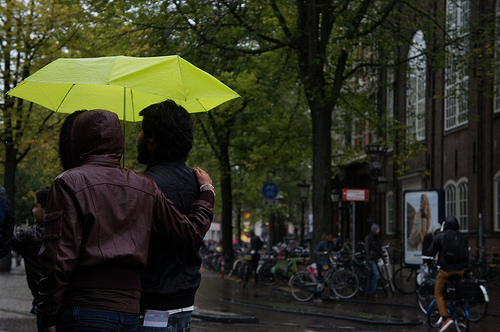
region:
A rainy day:
[12, 10, 472, 310]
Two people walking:
[16, 105, 236, 313]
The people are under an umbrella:
[17, 39, 228, 316]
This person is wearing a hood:
[52, 100, 128, 175]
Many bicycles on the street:
[219, 201, 361, 320]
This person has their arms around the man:
[42, 98, 154, 325]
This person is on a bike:
[410, 209, 479, 316]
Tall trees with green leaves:
[218, 9, 358, 256]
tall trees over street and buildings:
[1, 2, 407, 232]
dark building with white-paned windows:
[311, 0, 491, 291]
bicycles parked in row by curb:
[206, 230, 396, 305]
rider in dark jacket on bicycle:
[406, 212, 496, 323]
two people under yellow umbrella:
[10, 26, 240, 321]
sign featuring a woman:
[397, 182, 439, 263]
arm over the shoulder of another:
[17, 95, 218, 325]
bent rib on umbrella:
[6, 45, 237, 120]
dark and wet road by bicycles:
[177, 252, 372, 324]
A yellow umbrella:
[76, 62, 186, 79]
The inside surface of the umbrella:
[83, 91, 113, 106]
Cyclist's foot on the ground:
[441, 326, 445, 329]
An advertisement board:
[407, 193, 437, 230]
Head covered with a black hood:
[448, 218, 457, 226]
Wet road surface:
[267, 313, 282, 319]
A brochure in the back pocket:
[148, 311, 163, 326]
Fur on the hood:
[61, 128, 68, 155]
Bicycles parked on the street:
[278, 247, 301, 262]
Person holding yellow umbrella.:
[45, 39, 186, 94]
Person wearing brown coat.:
[83, 182, 144, 264]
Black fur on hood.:
[57, 118, 82, 153]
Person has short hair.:
[153, 118, 193, 158]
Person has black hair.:
[149, 102, 196, 149]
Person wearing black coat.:
[155, 175, 221, 281]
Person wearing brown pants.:
[426, 264, 453, 304]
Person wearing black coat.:
[436, 226, 456, 251]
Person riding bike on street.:
[413, 248, 469, 323]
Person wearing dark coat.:
[353, 225, 387, 255]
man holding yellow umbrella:
[4, 50, 239, 115]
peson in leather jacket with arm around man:
[34, 97, 218, 328]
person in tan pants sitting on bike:
[425, 213, 474, 323]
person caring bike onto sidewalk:
[288, 230, 361, 302]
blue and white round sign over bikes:
[260, 180, 280, 200]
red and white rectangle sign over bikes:
[340, 188, 369, 200]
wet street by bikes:
[229, 280, 266, 296]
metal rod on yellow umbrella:
[122, 88, 129, 165]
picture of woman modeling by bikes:
[406, 190, 439, 266]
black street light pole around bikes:
[295, 176, 313, 251]